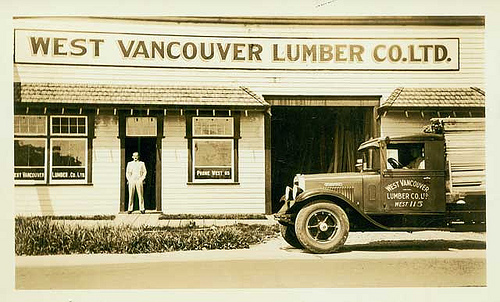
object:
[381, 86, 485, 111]
tiles roof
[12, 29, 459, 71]
sign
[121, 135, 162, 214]
door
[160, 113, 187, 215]
clap boards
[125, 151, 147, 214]
man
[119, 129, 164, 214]
doorway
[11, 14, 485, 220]
building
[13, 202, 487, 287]
ground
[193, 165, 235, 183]
sign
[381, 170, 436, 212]
door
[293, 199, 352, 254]
tire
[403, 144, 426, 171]
person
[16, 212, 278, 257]
plants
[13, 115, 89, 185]
windows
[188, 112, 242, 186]
windows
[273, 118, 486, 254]
lorry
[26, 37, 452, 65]
letters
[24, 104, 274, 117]
light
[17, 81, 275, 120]
shingled awning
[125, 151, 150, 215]
standing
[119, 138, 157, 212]
open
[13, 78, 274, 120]
roof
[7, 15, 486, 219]
wall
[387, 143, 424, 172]
window